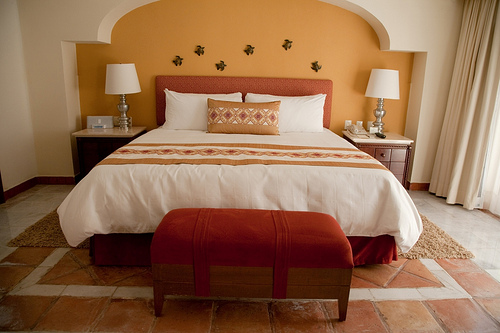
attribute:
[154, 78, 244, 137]
pillow — white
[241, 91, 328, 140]
pillow — white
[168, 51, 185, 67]
turtle — decor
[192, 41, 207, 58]
turtle — decor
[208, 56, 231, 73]
turtle — decor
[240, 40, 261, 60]
turtle — decor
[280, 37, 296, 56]
turtle — decor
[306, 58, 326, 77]
turtle — decor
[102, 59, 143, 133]
lamp — silver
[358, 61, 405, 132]
lamp — silver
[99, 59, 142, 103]
shade — white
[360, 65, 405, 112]
shade — white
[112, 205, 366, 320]
ottoman — red, wooden, brown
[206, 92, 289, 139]
pillows — orange, designer, long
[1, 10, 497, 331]
room — decorated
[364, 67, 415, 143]
lamp — silver, metal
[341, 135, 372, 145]
cord — white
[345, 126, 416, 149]
surface — white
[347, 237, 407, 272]
bedskirt — red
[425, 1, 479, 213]
curtains — offwhite, hanging, long, white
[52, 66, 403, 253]
bed — big, white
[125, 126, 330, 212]
sheets — orange, white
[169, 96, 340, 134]
two — white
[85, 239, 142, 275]
tuft — orange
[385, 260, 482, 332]
tiles — brown, white, tiled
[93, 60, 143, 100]
lamp — white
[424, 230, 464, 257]
rug — fuzzy, brown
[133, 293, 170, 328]
leg — wood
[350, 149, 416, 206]
table — wooden, white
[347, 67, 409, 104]
lampshade — white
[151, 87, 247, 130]
pillow — long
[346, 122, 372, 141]
telephone — white